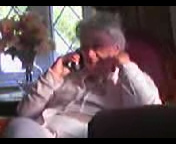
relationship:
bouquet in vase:
[0, 10, 55, 59] [15, 60, 43, 94]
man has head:
[1, 13, 161, 138] [69, 10, 122, 74]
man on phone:
[0, 14, 167, 141] [62, 40, 103, 72]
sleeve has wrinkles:
[16, 65, 65, 118] [25, 68, 53, 104]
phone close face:
[71, 49, 84, 71] [81, 26, 117, 76]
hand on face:
[110, 50, 130, 68] [74, 13, 127, 76]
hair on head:
[74, 15, 127, 51] [72, 15, 130, 82]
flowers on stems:
[0, 11, 60, 68] [24, 67, 33, 84]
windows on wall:
[4, 7, 92, 95] [1, 0, 174, 138]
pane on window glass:
[53, 8, 80, 49] [0, 8, 80, 80]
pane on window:
[0, 5, 12, 23] [0, 5, 42, 77]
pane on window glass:
[53, 5, 80, 55] [44, 89, 59, 113]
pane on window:
[53, 5, 80, 55] [0, 8, 88, 91]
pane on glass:
[53, 5, 80, 55] [53, 5, 81, 68]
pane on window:
[53, 5, 80, 55] [55, 8, 69, 45]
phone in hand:
[71, 49, 84, 71] [51, 52, 80, 76]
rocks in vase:
[18, 81, 35, 87] [13, 76, 38, 95]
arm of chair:
[87, 104, 175, 138] [69, 35, 174, 142]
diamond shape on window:
[53, 6, 81, 49] [0, 5, 96, 87]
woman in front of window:
[3, 10, 162, 140] [0, 8, 88, 91]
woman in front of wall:
[3, 10, 162, 140] [99, 6, 175, 98]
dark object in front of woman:
[88, 105, 174, 137] [3, 10, 162, 140]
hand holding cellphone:
[50, 48, 85, 75] [66, 47, 87, 71]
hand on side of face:
[110, 50, 130, 68] [79, 27, 119, 75]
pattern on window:
[53, 5, 80, 48] [49, 5, 83, 63]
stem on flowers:
[5, 47, 32, 82] [1, 14, 54, 90]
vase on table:
[16, 80, 40, 96] [1, 87, 37, 117]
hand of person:
[52, 48, 85, 74] [6, 11, 166, 143]